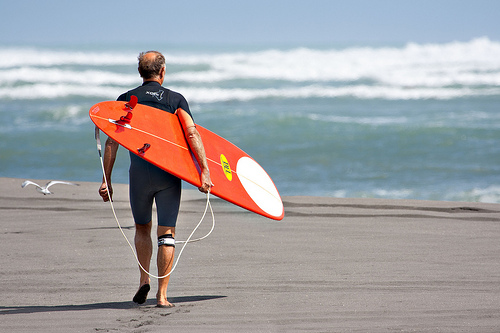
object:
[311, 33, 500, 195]
water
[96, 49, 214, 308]
man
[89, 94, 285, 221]
board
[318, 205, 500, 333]
sand